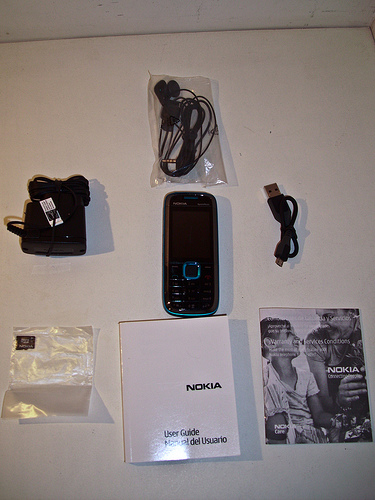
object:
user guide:
[117, 315, 239, 465]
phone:
[160, 190, 220, 316]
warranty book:
[258, 308, 372, 446]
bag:
[2, 325, 97, 417]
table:
[0, 25, 373, 495]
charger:
[8, 175, 89, 258]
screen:
[171, 208, 212, 262]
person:
[260, 316, 321, 444]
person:
[305, 308, 370, 442]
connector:
[264, 182, 300, 268]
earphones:
[153, 78, 217, 177]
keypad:
[167, 262, 215, 311]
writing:
[164, 427, 228, 450]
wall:
[1, 0, 374, 38]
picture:
[260, 307, 374, 445]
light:
[156, 435, 189, 462]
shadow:
[218, 194, 235, 314]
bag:
[147, 71, 223, 191]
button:
[183, 262, 199, 279]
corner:
[121, 445, 136, 467]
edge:
[1, 22, 375, 42]